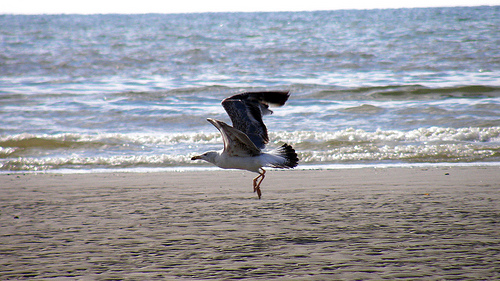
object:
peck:
[187, 154, 201, 161]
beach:
[0, 166, 499, 280]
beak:
[188, 154, 203, 161]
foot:
[251, 177, 259, 194]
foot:
[254, 187, 261, 200]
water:
[0, 0, 499, 176]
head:
[189, 150, 215, 162]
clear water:
[0, 0, 499, 174]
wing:
[205, 117, 258, 156]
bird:
[189, 89, 299, 200]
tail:
[267, 142, 302, 171]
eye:
[202, 153, 209, 157]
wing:
[219, 88, 294, 150]